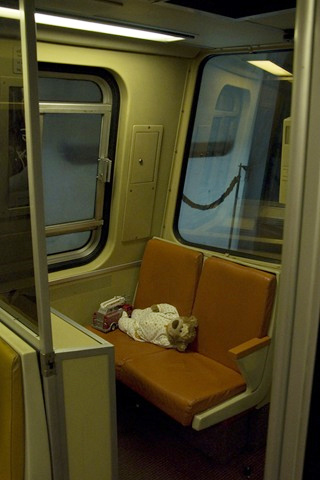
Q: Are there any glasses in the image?
A: No, there are no glasses.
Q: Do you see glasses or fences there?
A: No, there are no glasses or fences.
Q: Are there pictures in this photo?
A: No, there are no pictures.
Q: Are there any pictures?
A: No, there are no pictures.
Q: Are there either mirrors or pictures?
A: No, there are no pictures or mirrors.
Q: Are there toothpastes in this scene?
A: No, there are no toothpastes.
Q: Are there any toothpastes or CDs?
A: No, there are no toothpastes or cds.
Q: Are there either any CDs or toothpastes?
A: No, there are no toothpastes or cds.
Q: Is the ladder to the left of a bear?
A: Yes, the ladder is to the left of a bear.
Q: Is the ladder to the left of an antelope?
A: No, the ladder is to the left of a bear.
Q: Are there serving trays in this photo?
A: No, there are no serving trays.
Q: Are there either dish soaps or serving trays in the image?
A: No, there are no serving trays or dish soaps.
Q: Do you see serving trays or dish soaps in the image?
A: No, there are no serving trays or dish soaps.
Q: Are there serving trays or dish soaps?
A: No, there are no serving trays or dish soaps.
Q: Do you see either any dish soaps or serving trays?
A: No, there are no serving trays or dish soaps.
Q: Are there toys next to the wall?
A: Yes, there are toys next to the wall.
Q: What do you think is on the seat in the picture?
A: The toys are on the seat.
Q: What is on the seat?
A: The toys are on the seat.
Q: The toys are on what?
A: The toys are on the seat.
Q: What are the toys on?
A: The toys are on the seat.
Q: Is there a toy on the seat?
A: Yes, there are toys on the seat.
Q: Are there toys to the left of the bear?
A: Yes, there are toys to the left of the bear.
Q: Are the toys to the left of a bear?
A: Yes, the toys are to the left of a bear.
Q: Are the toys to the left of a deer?
A: No, the toys are to the left of a bear.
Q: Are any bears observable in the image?
A: Yes, there is a bear.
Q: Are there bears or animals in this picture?
A: Yes, there is a bear.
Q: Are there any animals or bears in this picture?
A: Yes, there is a bear.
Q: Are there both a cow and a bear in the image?
A: No, there is a bear but no cows.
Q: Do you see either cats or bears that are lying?
A: Yes, the bear is lying.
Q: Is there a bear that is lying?
A: Yes, there is a bear that is lying.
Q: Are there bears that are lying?
A: Yes, there is a bear that is lying.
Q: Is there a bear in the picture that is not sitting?
A: Yes, there is a bear that is lying.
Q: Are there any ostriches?
A: No, there are no ostriches.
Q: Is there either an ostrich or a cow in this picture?
A: No, there are no ostriches or cows.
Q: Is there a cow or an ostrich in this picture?
A: No, there are no ostriches or cows.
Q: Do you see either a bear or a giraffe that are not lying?
A: No, there is a bear but it is lying.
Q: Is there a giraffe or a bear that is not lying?
A: No, there is a bear but it is lying.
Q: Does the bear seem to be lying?
A: Yes, the bear is lying.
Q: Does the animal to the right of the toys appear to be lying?
A: Yes, the bear is lying.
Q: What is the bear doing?
A: The bear is lying.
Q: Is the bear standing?
A: No, the bear is lying.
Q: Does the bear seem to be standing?
A: No, the bear is lying.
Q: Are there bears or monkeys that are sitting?
A: No, there is a bear but it is lying.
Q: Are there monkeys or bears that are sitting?
A: No, there is a bear but it is lying.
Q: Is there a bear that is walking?
A: No, there is a bear but it is lying.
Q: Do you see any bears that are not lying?
A: No, there is a bear but it is lying.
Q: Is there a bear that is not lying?
A: No, there is a bear but it is lying.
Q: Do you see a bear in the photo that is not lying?
A: No, there is a bear but it is lying.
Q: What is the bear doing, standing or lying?
A: The bear is lying.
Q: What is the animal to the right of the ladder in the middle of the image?
A: The animal is a bear.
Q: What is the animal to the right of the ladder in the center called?
A: The animal is a bear.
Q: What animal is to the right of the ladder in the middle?
A: The animal is a bear.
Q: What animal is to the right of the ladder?
A: The animal is a bear.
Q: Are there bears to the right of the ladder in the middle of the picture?
A: Yes, there is a bear to the right of the ladder.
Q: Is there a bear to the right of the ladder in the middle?
A: Yes, there is a bear to the right of the ladder.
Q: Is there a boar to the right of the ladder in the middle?
A: No, there is a bear to the right of the ladder.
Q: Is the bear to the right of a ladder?
A: Yes, the bear is to the right of a ladder.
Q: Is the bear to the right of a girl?
A: No, the bear is to the right of a ladder.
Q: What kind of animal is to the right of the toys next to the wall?
A: The animal is a bear.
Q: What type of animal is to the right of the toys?
A: The animal is a bear.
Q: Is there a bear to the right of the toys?
A: Yes, there is a bear to the right of the toys.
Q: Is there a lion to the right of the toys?
A: No, there is a bear to the right of the toys.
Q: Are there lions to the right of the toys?
A: No, there is a bear to the right of the toys.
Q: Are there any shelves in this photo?
A: No, there are no shelves.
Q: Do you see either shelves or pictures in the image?
A: No, there are no shelves or pictures.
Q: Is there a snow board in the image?
A: No, there are no snowboards.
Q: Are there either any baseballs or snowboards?
A: No, there are no snowboards or baseballs.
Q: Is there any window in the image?
A: Yes, there is a window.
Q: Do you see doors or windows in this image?
A: Yes, there is a window.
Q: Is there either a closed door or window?
A: Yes, there is a closed window.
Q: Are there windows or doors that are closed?
A: Yes, the window is closed.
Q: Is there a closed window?
A: Yes, there is a closed window.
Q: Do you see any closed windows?
A: Yes, there is a closed window.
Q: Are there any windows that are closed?
A: Yes, there is a window that is closed.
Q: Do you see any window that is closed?
A: Yes, there is a window that is closed.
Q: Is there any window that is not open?
A: Yes, there is an closed window.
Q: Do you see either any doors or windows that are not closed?
A: No, there is a window but it is closed.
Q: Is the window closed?
A: Yes, the window is closed.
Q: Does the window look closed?
A: Yes, the window is closed.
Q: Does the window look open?
A: No, the window is closed.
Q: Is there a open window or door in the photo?
A: No, there is a window but it is closed.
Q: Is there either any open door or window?
A: No, there is a window but it is closed.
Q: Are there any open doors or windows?
A: No, there is a window but it is closed.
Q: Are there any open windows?
A: No, there is a window but it is closed.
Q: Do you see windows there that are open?
A: No, there is a window but it is closed.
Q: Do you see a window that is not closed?
A: No, there is a window but it is closed.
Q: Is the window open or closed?
A: The window is closed.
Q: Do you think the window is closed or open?
A: The window is closed.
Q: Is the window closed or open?
A: The window is closed.